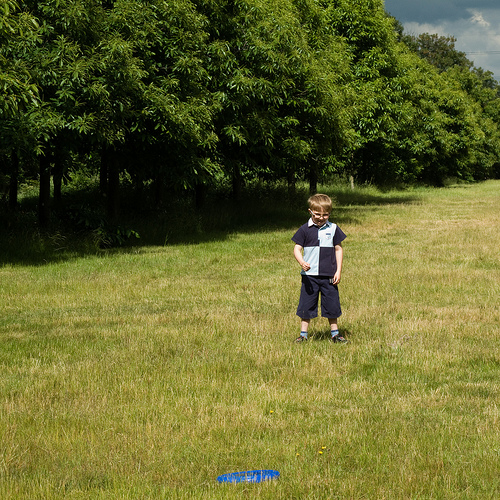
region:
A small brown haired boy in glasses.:
[290, 193, 347, 345]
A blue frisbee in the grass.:
[215, 466, 280, 483]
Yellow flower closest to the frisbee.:
[291, 452, 302, 459]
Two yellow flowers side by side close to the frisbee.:
[318, 441, 326, 454]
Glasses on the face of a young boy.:
[308, 205, 330, 220]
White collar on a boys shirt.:
[305, 215, 332, 230]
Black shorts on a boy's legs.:
[294, 274, 343, 320]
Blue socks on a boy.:
[297, 329, 341, 337]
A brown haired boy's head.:
[306, 192, 331, 224]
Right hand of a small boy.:
[299, 260, 314, 272]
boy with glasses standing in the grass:
[292, 189, 347, 354]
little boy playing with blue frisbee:
[197, 191, 350, 486]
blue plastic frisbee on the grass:
[208, 466, 285, 486]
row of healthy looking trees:
[5, 0, 495, 229]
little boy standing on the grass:
[284, 190, 359, 360]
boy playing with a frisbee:
[207, 188, 348, 493]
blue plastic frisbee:
[212, 463, 284, 486]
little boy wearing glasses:
[292, 193, 344, 342]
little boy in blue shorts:
[292, 191, 347, 348]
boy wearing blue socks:
[293, 326, 348, 344]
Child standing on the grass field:
[288, 193, 350, 344]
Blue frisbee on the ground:
[210, 468, 280, 483]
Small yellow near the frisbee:
[290, 443, 326, 458]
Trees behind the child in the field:
[2, 0, 495, 216]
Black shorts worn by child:
[295, 275, 342, 322]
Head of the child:
[306, 194, 334, 226]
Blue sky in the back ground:
[376, 0, 498, 72]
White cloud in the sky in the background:
[392, 12, 497, 79]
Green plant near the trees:
[22, 212, 137, 259]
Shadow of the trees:
[2, 177, 419, 271]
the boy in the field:
[285, 183, 352, 353]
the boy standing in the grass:
[290, 185, 350, 350]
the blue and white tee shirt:
[290, 216, 347, 277]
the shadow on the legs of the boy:
[300, 272, 316, 299]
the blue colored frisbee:
[213, 451, 284, 489]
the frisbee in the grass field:
[211, 460, 281, 490]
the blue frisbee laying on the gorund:
[205, 455, 287, 496]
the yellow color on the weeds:
[308, 443, 330, 483]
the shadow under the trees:
[3, 189, 293, 274]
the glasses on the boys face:
[307, 190, 335, 230]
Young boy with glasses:
[289, 190, 351, 348]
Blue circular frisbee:
[212, 462, 283, 488]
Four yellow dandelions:
[264, 402, 334, 466]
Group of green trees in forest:
[4, 16, 498, 216]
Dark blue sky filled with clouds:
[387, 3, 498, 76]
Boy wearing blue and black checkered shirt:
[284, 188, 357, 348]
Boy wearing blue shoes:
[288, 188, 349, 350]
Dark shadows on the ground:
[1, 177, 421, 262]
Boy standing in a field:
[5, 184, 497, 498]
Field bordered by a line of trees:
[5, 9, 498, 494]